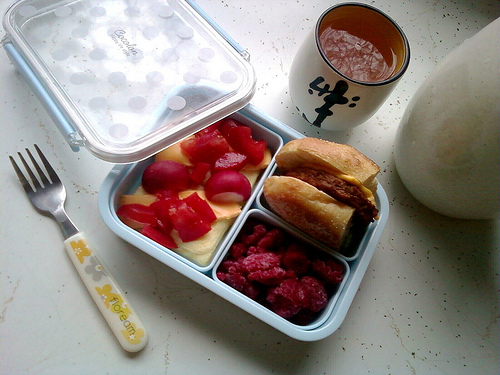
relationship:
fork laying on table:
[8, 142, 148, 356] [3, 3, 496, 370]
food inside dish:
[118, 109, 383, 327] [91, 74, 390, 357]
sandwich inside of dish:
[260, 136, 382, 251] [91, 74, 390, 357]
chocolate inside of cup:
[317, 18, 395, 85] [288, 3, 412, 133]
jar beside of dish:
[396, 16, 499, 224] [91, 74, 390, 357]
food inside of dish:
[118, 109, 383, 327] [91, 74, 390, 357]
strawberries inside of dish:
[221, 221, 346, 319] [91, 74, 390, 357]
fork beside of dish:
[8, 142, 148, 356] [91, 74, 390, 357]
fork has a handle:
[8, 142, 148, 356] [63, 232, 153, 358]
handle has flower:
[63, 232, 153, 358] [66, 239, 91, 264]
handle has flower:
[63, 232, 153, 358] [82, 256, 108, 284]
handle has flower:
[63, 232, 153, 358] [94, 282, 115, 304]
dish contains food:
[91, 74, 390, 357] [118, 109, 383, 327]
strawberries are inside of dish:
[221, 221, 346, 319] [91, 74, 390, 357]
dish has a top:
[91, 74, 390, 357] [2, 0, 255, 166]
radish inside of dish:
[202, 167, 250, 206] [91, 74, 390, 357]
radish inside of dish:
[142, 160, 190, 195] [91, 74, 390, 357]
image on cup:
[296, 71, 358, 132] [288, 3, 412, 133]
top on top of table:
[2, 0, 255, 166] [3, 3, 496, 370]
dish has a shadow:
[91, 74, 390, 357] [99, 240, 328, 373]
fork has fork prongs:
[8, 142, 148, 356] [6, 142, 74, 240]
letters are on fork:
[111, 296, 138, 339] [8, 142, 148, 356]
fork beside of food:
[8, 142, 148, 356] [118, 109, 383, 327]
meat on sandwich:
[282, 166, 379, 224] [260, 136, 382, 251]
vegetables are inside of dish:
[117, 116, 266, 251] [91, 74, 390, 357]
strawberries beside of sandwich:
[221, 221, 346, 319] [260, 136, 382, 251]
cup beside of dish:
[288, 3, 412, 133] [91, 74, 390, 357]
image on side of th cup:
[296, 71, 358, 132] [288, 3, 412, 133]